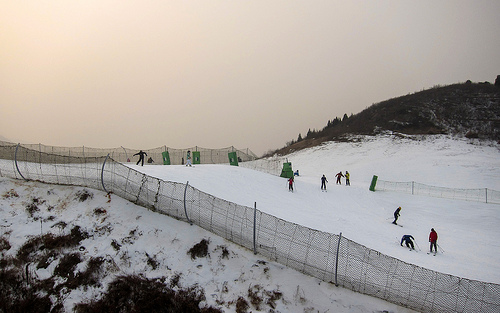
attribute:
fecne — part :
[0, 146, 484, 306]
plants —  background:
[17, 219, 206, 307]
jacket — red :
[425, 231, 442, 243]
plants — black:
[14, 204, 160, 288]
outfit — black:
[314, 171, 333, 191]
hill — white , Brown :
[155, 87, 483, 285]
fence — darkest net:
[4, 147, 474, 310]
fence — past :
[31, 180, 361, 301]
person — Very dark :
[422, 222, 448, 254]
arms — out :
[334, 170, 347, 189]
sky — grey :
[3, 5, 473, 158]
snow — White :
[203, 166, 244, 198]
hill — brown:
[288, 80, 477, 217]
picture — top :
[4, 3, 484, 304]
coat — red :
[429, 233, 439, 242]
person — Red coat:
[424, 224, 443, 253]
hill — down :
[250, 81, 484, 256]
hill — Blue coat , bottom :
[274, 77, 484, 230]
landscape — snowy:
[12, 142, 479, 303]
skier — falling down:
[273, 160, 450, 260]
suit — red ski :
[427, 232, 440, 247]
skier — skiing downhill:
[314, 163, 444, 256]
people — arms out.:
[287, 156, 441, 254]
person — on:
[128, 145, 152, 173]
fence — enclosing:
[171, 185, 267, 250]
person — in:
[385, 225, 421, 259]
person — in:
[395, 228, 421, 262]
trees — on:
[319, 112, 359, 135]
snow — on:
[394, 146, 451, 178]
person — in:
[421, 224, 451, 262]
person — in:
[419, 220, 457, 263]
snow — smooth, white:
[3, 130, 495, 311]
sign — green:
[281, 161, 292, 179]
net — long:
[3, 144, 497, 311]